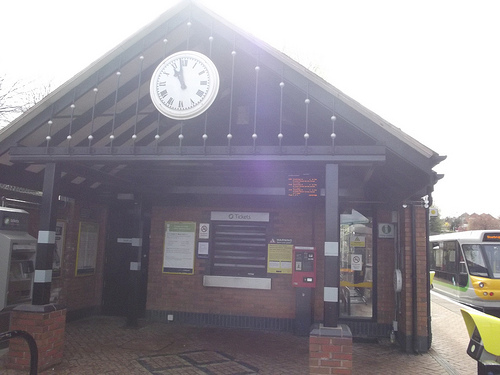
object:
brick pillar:
[399, 207, 432, 355]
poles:
[28, 164, 61, 304]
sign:
[160, 218, 198, 276]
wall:
[60, 162, 394, 337]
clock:
[149, 50, 221, 121]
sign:
[486, 235, 499, 239]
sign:
[288, 177, 319, 197]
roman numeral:
[159, 60, 207, 107]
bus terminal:
[1, 0, 447, 363]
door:
[100, 201, 143, 319]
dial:
[170, 59, 188, 89]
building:
[0, 1, 445, 355]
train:
[427, 228, 499, 315]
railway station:
[0, 0, 499, 375]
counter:
[143, 201, 337, 329]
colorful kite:
[0, 0, 500, 374]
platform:
[0, 0, 499, 375]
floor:
[0, 314, 497, 373]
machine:
[291, 245, 317, 287]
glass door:
[338, 220, 376, 320]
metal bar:
[110, 65, 121, 153]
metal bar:
[132, 52, 136, 140]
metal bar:
[226, 46, 233, 153]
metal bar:
[250, 62, 259, 151]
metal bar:
[276, 81, 284, 152]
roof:
[1, 0, 447, 186]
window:
[3, 197, 39, 238]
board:
[148, 188, 300, 320]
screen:
[284, 170, 321, 199]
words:
[289, 177, 317, 188]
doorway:
[89, 316, 149, 343]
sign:
[75, 220, 100, 279]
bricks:
[306, 325, 354, 374]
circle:
[180, 85, 187, 90]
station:
[427, 215, 499, 371]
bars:
[0, 0, 440, 155]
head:
[458, 229, 500, 315]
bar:
[323, 161, 338, 328]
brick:
[7, 307, 64, 374]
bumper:
[489, 292, 493, 297]